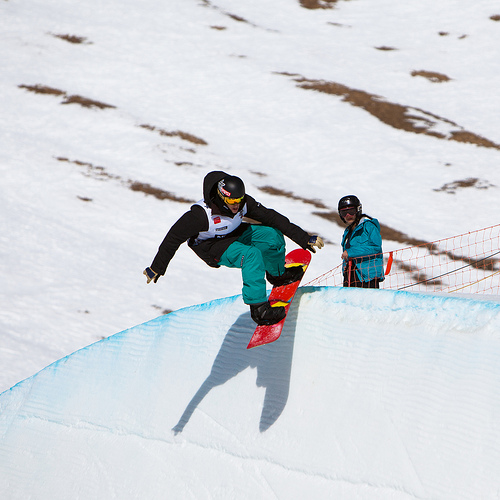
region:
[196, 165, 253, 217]
face of the person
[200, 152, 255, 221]
a helmet wearing by person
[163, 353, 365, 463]
shadow on the ice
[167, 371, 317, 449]
shadow of the person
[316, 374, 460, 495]
sun shine on the ice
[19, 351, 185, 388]
a blue ice in the ice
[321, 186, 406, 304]
a man walking in ice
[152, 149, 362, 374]
a man jumping in ice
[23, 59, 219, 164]
a brown marks in ice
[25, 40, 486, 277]
the snow is on the ground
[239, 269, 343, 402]
the man has a red snowboard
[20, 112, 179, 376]
tracks are in the snow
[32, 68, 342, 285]
dirt is in the snow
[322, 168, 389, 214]
the man is wearing a helmet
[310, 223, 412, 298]
the man has a blue jacket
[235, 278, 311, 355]
the man has ski boots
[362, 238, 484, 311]
a flag is on the fence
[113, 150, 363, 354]
the man on the snowboard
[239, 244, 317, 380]
the snowboard is red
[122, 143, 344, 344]
the man is snowboarding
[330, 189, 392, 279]
the man by the net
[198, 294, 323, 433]
the shadow under the man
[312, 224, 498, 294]
the net is orange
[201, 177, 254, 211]
man wearing helmet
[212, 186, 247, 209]
man wearing goggles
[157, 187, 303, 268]
man wearing black jacket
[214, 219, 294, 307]
aqua ski pants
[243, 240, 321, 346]
snow board is red with yellow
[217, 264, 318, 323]
ski boots are black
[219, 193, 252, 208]
skier is wearing goggles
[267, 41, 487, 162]
patches of missing snow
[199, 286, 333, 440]
shadow of the skier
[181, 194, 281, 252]
white bib on the skier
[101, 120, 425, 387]
two people snowboarding on pipe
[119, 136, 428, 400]
the rim of the pipe is blue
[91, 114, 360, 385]
the snowboarder wears a helmet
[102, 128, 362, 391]
the snowboard is red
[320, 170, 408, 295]
he has a helmet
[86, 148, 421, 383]
the helmets are black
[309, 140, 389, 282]
his jacket is blue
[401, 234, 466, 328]
the fence is orange netting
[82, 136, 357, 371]
the snowboarder does a trick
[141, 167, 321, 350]
a person standing on a snowboard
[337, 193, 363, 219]
a black colored helmet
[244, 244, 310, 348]
a red and yellow snowboard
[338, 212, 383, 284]
a green colored coat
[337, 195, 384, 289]
a person wearing black goggles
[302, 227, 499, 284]
an orange colored net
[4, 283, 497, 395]
a blue line in the snow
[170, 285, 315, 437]
shadow of a person on the ground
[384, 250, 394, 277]
orange ribbon on the net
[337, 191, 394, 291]
a man standing behind a hill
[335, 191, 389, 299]
a man in a blue jacket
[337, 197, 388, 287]
a guy in a black helmet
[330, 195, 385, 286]
a man behind a net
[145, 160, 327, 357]
a man on a reddish snowboard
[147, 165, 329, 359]
a man snowboarding on a hill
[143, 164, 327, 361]
a guy riding on a snowy hill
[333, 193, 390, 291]
a man in a large blue jacket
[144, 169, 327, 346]
Man riding a snowboard